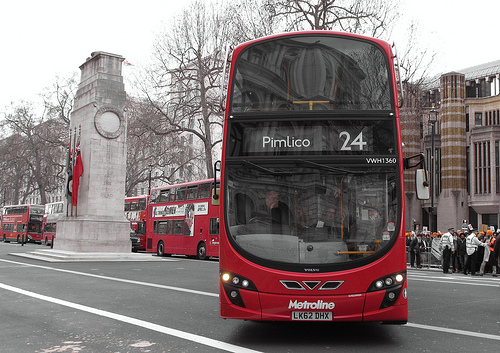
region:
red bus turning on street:
[210, 31, 403, 311]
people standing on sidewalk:
[413, 216, 498, 276]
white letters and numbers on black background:
[255, 124, 362, 155]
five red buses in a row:
[8, 32, 409, 320]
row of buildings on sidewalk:
[5, 63, 486, 235]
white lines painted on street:
[4, 253, 499, 340]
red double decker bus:
[212, 38, 419, 315]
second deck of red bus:
[223, 34, 385, 109]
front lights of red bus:
[220, 266, 402, 309]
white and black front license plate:
[290, 310, 332, 324]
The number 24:
[333, 128, 367, 149]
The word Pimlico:
[256, 134, 315, 147]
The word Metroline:
[286, 300, 338, 310]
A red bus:
[207, 32, 419, 339]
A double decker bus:
[216, 25, 417, 338]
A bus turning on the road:
[220, 30, 415, 340]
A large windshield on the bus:
[223, 154, 400, 274]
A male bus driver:
[252, 190, 287, 223]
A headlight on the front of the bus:
[394, 273, 404, 285]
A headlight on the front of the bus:
[217, 271, 229, 281]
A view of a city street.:
[0, 3, 498, 351]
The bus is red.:
[207, 20, 433, 350]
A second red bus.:
[140, 170, 215, 255]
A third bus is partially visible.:
[120, 185, 140, 245]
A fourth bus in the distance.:
[0, 195, 40, 245]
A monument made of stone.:
[52, 42, 133, 252]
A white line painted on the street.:
[0, 272, 270, 347]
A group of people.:
[405, 225, 495, 275]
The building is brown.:
[402, 61, 497, 217]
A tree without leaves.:
[133, 10, 226, 181]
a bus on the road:
[175, 30, 460, 350]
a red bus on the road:
[160, 16, 483, 346]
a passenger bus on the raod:
[165, 21, 495, 336]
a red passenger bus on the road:
[150, 25, 386, 346]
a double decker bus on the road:
[189, 27, 450, 351]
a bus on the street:
[180, 29, 480, 349]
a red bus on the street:
[192, 23, 449, 322]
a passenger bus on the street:
[172, 15, 497, 346]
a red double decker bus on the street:
[172, 18, 435, 340]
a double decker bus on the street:
[185, 33, 436, 351]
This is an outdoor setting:
[32, 62, 480, 282]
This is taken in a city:
[32, 40, 441, 325]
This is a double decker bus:
[182, 29, 434, 336]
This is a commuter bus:
[172, 40, 402, 339]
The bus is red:
[195, 32, 484, 352]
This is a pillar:
[38, 50, 173, 264]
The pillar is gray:
[51, 76, 161, 288]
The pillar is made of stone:
[32, 39, 178, 308]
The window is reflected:
[204, 83, 396, 343]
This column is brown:
[434, 68, 498, 189]